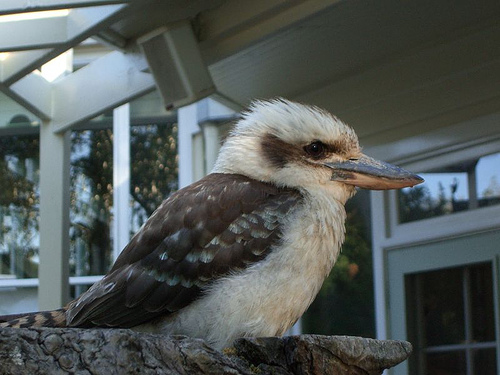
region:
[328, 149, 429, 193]
beak of a bird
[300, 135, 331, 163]
eye of a bird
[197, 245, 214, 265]
white feathers on a bird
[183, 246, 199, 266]
white feathers on a bird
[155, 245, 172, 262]
white feathers on a bird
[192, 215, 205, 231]
white feathers on a bird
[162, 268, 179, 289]
white feathers on a bird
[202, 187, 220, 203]
white feathers on a bird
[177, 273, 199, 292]
white feathers on a bird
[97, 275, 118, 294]
white feathers on a bird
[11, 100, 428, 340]
a bird sitting down outside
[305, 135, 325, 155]
an eye of a bird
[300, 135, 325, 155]
the bird has brown eyes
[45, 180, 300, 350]
feathers of a bird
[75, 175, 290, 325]
the feathers are brown in color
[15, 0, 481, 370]
a building near the animal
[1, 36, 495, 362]
windows on the building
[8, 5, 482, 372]
the building is a white color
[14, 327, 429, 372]
sitting place for the bird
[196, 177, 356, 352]
front part of the bird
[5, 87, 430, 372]
a kookaburra on a perch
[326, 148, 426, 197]
large thick beak of a kookaburra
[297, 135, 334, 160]
black eye of a kookaburra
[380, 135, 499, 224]
reflection in some windows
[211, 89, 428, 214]
white feathery head of a kookaburra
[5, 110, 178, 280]
trees behind windows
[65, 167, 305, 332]
feathered wing of a kookaburra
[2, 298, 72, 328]
brown and black tail of a kookaburra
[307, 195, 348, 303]
feathered breast of a kookaburra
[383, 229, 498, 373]
a glass paneled door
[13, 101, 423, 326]
Bird sitting on stone wall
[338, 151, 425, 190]
Short thick beak of bird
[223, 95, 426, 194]
Small head of bird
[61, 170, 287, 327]
Black feathers of bird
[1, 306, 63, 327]
Striped tail of bird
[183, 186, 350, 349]
White underbelly of bird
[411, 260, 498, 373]
Black panes on a door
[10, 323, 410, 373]
Wall made of stones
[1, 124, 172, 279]
Trees' reflection on window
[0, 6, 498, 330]
Building painted in white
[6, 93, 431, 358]
a bird is resting here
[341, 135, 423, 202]
the birds beak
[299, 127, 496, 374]
a big window is in the background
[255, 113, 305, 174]
the bird has a brown spot on its head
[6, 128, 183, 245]
some trees are in the background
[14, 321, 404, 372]
the bird is resting on some wood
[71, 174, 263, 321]
the birds wings are brown with a few white spots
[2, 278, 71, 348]
these are the birds tail feathers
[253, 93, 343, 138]
the top of the birds head is white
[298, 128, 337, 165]
the birds eye is very dark in color